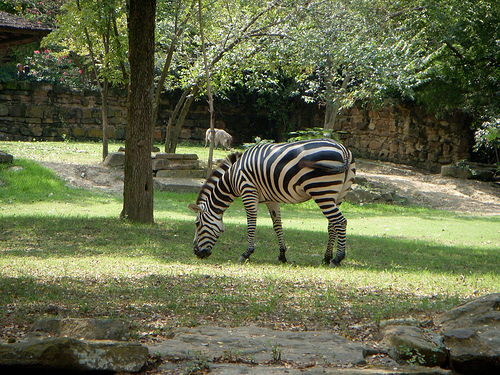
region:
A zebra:
[258, 117, 343, 274]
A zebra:
[283, 128, 318, 249]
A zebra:
[221, 55, 312, 352]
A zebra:
[264, 138, 293, 289]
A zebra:
[261, 96, 322, 369]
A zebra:
[238, 106, 290, 308]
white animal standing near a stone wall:
[205, 127, 232, 150]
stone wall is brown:
[0, 68, 274, 142]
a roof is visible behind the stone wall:
[0, 10, 51, 53]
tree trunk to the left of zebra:
[124, 2, 157, 222]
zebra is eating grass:
[187, 138, 357, 269]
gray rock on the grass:
[0, 337, 152, 374]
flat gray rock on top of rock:
[155, 152, 200, 162]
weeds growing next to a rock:
[390, 343, 437, 365]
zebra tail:
[300, 159, 350, 176]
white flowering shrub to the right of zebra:
[473, 115, 498, 152]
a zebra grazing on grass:
[183, 132, 362, 274]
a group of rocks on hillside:
[4, 312, 499, 372]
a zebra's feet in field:
[241, 213, 348, 272]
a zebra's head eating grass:
[186, 202, 223, 259]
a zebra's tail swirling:
[288, 136, 350, 178]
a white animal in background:
[203, 127, 241, 149]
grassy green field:
[4, 180, 497, 302]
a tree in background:
[11, 1, 409, 213]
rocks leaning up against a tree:
[106, 80, 201, 165]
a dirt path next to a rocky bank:
[329, 102, 499, 225]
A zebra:
[180, 101, 408, 372]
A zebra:
[198, 113, 341, 298]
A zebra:
[241, 183, 302, 220]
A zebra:
[171, 151, 303, 232]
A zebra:
[196, 161, 280, 220]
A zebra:
[226, 148, 331, 220]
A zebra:
[231, 160, 292, 210]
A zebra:
[236, 158, 429, 310]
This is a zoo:
[6, 10, 478, 365]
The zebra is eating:
[161, 119, 388, 314]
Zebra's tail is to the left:
[282, 117, 383, 261]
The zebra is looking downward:
[168, 140, 342, 271]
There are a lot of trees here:
[13, 4, 494, 259]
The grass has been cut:
[18, 205, 492, 339]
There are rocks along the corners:
[31, 265, 489, 373]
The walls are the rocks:
[18, 39, 492, 183]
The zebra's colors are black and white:
[161, 116, 372, 278]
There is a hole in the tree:
[135, 148, 157, 209]